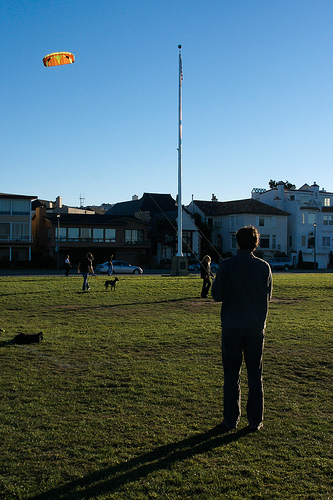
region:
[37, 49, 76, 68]
Yellow and orange parachute.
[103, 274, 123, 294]
A dog is standing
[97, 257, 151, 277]
Grey color is on road.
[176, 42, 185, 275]
White color pole standing straight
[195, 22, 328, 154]
sky is blue in color.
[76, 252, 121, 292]
The man is holding the dog.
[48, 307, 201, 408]
The grass is green in color.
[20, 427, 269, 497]
The shadow is in the ground.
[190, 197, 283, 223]
The roof is brown in color.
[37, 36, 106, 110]
Parachute is flying in the sky.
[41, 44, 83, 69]
an orange and yellow kite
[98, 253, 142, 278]
silver car parked on side of the road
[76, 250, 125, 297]
a man walking a dog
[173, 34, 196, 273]
a tall flag pole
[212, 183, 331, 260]
a house painted white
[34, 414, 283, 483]
shadow of persons legs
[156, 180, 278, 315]
a person flying a kite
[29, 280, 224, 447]
a field of grass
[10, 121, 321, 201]
a clear sky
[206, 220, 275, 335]
person wearing a jacket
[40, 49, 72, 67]
orange and yellow kite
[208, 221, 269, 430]
Person flying a kite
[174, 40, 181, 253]
tall white flag pole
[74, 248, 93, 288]
person walking pet dog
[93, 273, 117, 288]
dog on orange leash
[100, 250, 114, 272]
person walking near street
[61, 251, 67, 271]
person walking near street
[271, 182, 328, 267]
three story white house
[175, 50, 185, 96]
american flag flat against pole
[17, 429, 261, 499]
shadow from person's legs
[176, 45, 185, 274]
Flag pole in the park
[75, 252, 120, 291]
Woman walking a dog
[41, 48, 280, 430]
Man flying a kite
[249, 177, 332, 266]
White apartment building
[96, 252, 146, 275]
Man walking in the park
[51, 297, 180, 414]
Freshly cut grass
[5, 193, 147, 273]
Apartment buildings next to the park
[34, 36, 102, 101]
Bright orange kite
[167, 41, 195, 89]
The stars and stripes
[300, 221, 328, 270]
Street light in front of apartments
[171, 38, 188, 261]
An American flag is on the flagpole.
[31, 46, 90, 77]
A large kite is in the air.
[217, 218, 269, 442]
This man is flying the kite.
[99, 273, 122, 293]
A small dog is walking on the grass.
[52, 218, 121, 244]
Five windows in a row.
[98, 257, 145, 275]
Someone is near the car.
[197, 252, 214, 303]
The person is looking up at the kite.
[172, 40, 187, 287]
That is a tall flagpole.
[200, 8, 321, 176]
The sky is blue.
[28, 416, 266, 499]
The shadow is behind the man.